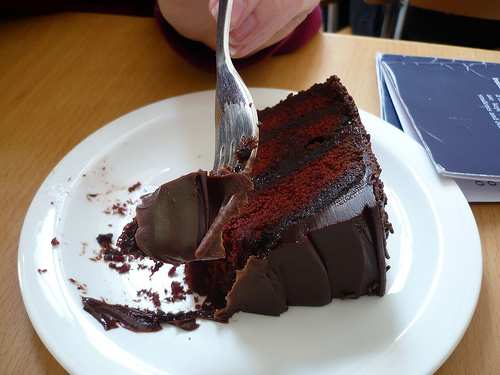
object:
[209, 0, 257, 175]
fork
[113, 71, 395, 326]
cake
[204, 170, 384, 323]
chocolate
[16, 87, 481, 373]
plate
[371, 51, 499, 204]
book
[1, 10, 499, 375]
table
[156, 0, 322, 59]
hand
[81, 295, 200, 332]
smudge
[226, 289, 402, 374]
shadow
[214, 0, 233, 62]
handle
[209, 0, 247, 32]
nails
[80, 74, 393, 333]
frosting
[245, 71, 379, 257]
lines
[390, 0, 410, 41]
pole